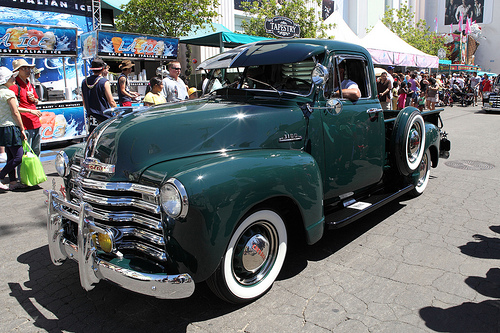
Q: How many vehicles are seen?
A: Two.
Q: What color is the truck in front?
A: Green.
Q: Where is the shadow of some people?
A: Bottom right corner.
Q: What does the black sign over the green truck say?
A: Tapestry.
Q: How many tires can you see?
A: Three.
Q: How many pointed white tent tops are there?
A: Two.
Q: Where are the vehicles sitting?
A: Street.